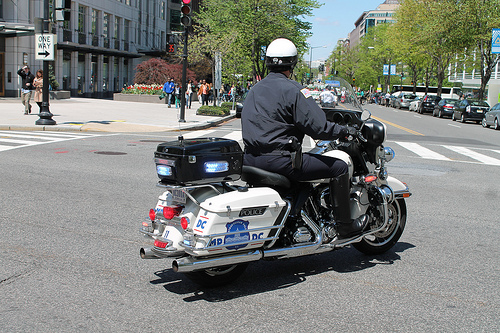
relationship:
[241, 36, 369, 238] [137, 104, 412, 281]
cop on motorcycle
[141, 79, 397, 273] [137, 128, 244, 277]
motorcycle has back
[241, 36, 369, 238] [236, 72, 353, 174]
cop wears black clothes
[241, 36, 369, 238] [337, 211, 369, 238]
cop wears boot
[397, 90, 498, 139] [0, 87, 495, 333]
car along road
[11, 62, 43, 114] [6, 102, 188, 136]
people on sidewalk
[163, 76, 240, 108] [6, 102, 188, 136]
people on sidewalk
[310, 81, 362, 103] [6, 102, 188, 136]
people on sidewalk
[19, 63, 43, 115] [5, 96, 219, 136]
couple on sidewalk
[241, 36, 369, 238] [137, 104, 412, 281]
cop riding motorcycle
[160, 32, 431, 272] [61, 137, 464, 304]
cop on intersection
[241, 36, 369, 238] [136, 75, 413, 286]
cop on motorcycle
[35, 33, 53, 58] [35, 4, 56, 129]
sign on pole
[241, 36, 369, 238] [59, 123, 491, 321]
cop on road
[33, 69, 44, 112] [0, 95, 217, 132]
people on sidewalk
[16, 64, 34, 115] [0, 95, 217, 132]
pedestrian on sidewalk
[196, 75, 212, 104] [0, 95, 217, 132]
person on sidewalk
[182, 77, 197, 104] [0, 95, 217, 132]
person on sidewalk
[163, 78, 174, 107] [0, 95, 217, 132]
people on sidewalk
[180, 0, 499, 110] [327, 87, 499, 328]
trees along road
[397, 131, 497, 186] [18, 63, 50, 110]
white paint for pedestrian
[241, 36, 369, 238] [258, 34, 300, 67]
cop has helmet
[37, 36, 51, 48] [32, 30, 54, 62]
one way on sign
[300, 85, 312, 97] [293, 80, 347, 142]
patch on sleeve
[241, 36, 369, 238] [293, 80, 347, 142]
cop has sleeve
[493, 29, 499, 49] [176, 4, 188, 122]
banner on pole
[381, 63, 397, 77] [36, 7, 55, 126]
banner on pole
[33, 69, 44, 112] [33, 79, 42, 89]
people has arms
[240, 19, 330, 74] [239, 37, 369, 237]
helmet on officer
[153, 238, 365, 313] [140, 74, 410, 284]
shadow of bikw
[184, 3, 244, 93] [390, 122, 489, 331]
trees along street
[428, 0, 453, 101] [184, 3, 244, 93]
trees along trees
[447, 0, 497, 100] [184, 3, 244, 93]
trees along trees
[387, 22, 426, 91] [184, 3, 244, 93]
trees along trees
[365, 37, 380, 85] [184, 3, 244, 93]
trees along trees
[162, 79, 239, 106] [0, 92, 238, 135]
crowd walking along sidewalk